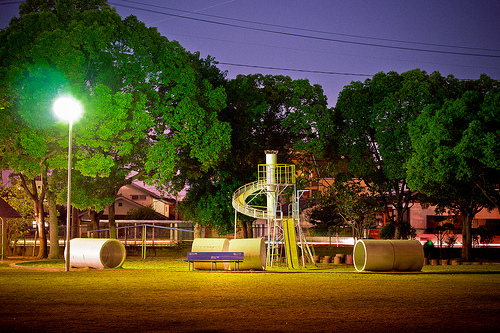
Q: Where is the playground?
A: In the park.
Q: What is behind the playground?
A: Trees.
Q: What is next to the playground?
A: A light.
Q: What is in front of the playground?
A: A bench.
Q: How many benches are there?
A: One.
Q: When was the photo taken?
A: In the afternoon.